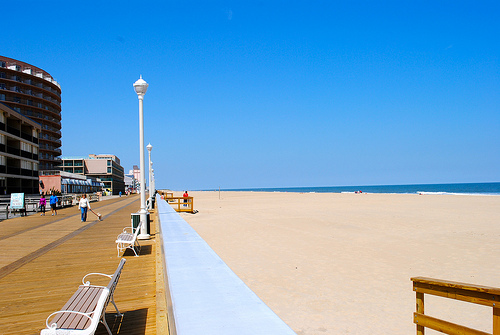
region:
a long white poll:
[120, 58, 170, 248]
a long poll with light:
[114, 69, 180, 256]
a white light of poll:
[128, 80, 160, 100]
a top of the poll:
[121, 68, 168, 99]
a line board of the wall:
[156, 194, 256, 334]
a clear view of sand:
[192, 189, 487, 326]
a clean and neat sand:
[182, 185, 499, 333]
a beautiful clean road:
[21, 203, 161, 328]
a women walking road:
[72, 190, 104, 230]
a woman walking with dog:
[68, 194, 115, 234]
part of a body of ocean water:
[257, 184, 497, 195]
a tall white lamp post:
[130, 75, 155, 239]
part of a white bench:
[42, 248, 132, 333]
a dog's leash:
[87, 207, 98, 217]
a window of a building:
[18, 139, 28, 150]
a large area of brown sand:
[160, 186, 497, 333]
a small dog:
[96, 210, 105, 217]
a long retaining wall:
[155, 188, 291, 333]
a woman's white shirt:
[75, 198, 90, 209]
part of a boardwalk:
[0, 191, 150, 333]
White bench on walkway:
[27, 246, 130, 327]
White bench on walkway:
[100, 212, 145, 257]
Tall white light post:
[127, 67, 153, 242]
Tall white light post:
[143, 136, 158, 212]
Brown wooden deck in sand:
[390, 262, 445, 327]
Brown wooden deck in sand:
[165, 190, 205, 210]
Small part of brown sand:
[215, 215, 271, 261]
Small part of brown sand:
[222, 188, 250, 224]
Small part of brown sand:
[260, 200, 318, 251]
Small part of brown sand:
[345, 194, 393, 231]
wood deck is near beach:
[28, 218, 153, 303]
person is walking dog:
[75, 192, 110, 224]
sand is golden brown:
[248, 204, 408, 260]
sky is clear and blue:
[264, 45, 451, 166]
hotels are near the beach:
[2, 53, 120, 198]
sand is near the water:
[275, 210, 391, 297]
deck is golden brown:
[28, 215, 119, 280]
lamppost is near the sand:
[128, 73, 155, 241]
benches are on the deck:
[50, 215, 142, 328]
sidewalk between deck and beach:
[154, 191, 296, 333]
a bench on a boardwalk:
[35, 253, 125, 334]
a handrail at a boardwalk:
[405, 274, 499, 334]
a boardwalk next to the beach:
[2, 191, 173, 333]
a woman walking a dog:
[75, 191, 92, 226]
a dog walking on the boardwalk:
[95, 212, 104, 222]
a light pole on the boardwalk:
[136, 69, 151, 243]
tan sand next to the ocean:
[160, 190, 496, 332]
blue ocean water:
[191, 181, 497, 194]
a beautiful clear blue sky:
[0, 0, 498, 188]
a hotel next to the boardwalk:
[1, 55, 67, 173]